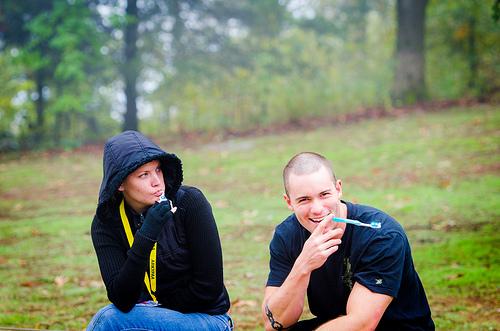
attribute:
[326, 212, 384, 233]
tooth brush — blue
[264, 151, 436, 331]
man — bald, blue, sitting, smiling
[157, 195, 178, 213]
tooth brush — blue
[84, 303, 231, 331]
pants — blue, denim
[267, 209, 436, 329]
tee shirt — black, wrinkly, short sleeved, navy blue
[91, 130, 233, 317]
coat — black, hooded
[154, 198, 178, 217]
gloves — black, fingerless, knitted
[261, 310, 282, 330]
tattoo — black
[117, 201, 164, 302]
lanyard — bright, yellow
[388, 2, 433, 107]
tree trunk — thick, light, brown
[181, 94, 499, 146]
leaves — dead, brown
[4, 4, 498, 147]
tree line — in background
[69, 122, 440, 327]
two people — outdoors